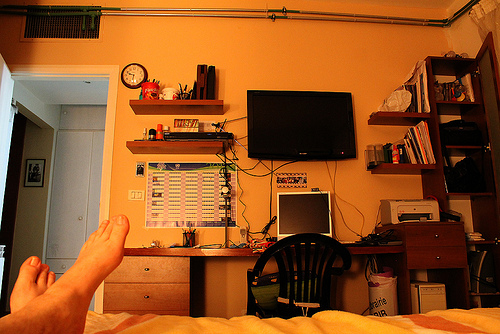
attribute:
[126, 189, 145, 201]
light switch — white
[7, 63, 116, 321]
trim — white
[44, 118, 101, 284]
doors — white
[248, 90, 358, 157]
television monitor — flat screen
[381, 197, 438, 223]
computer printer — white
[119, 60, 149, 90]
clock — white, brown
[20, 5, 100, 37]
air vent — grey, metal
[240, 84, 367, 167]
tv — black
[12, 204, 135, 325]
feet — bare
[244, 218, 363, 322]
chair — black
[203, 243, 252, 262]
desk — wooden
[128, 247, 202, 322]
drawer — brown